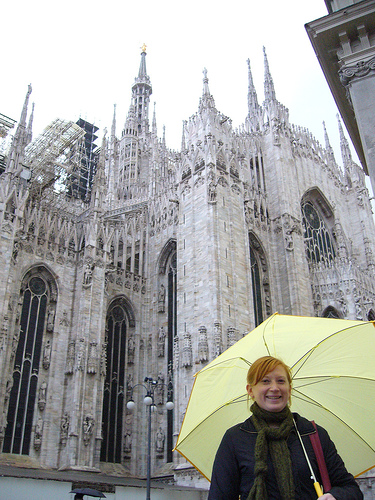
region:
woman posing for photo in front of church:
[14, 19, 353, 492]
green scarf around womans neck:
[243, 404, 301, 495]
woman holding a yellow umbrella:
[168, 299, 374, 479]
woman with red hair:
[231, 352, 296, 417]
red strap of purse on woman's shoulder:
[295, 412, 338, 497]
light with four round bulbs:
[126, 364, 177, 493]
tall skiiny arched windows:
[3, 255, 153, 459]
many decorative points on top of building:
[3, 36, 357, 164]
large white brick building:
[9, 139, 309, 454]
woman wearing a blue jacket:
[203, 349, 347, 495]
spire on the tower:
[255, 45, 282, 102]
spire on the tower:
[229, 46, 263, 104]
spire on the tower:
[196, 65, 213, 99]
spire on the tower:
[136, 34, 158, 82]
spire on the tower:
[161, 123, 166, 143]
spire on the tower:
[109, 100, 120, 131]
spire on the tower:
[23, 79, 35, 111]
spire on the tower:
[97, 121, 109, 142]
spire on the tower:
[318, 118, 331, 146]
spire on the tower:
[324, 107, 343, 141]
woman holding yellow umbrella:
[181, 303, 372, 498]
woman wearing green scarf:
[224, 351, 333, 499]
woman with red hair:
[217, 351, 325, 499]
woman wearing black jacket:
[209, 356, 332, 493]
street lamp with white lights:
[121, 375, 177, 498]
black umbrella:
[65, 483, 111, 498]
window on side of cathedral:
[91, 283, 145, 475]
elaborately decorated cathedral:
[1, 37, 371, 488]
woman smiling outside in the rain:
[219, 355, 339, 499]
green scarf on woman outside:
[245, 406, 299, 493]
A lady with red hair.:
[207, 355, 365, 498]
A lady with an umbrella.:
[172, 310, 374, 498]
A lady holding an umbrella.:
[171, 309, 374, 497]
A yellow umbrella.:
[171, 309, 374, 484]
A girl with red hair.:
[206, 355, 365, 498]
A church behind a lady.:
[1, 41, 373, 499]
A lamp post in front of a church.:
[125, 372, 176, 497]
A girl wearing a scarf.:
[205, 354, 363, 499]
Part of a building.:
[304, 1, 373, 191]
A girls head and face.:
[246, 355, 292, 410]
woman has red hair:
[250, 349, 284, 383]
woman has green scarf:
[248, 403, 305, 494]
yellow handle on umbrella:
[303, 481, 327, 497]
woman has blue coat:
[229, 420, 295, 484]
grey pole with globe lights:
[122, 379, 166, 494]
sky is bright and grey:
[167, 0, 267, 111]